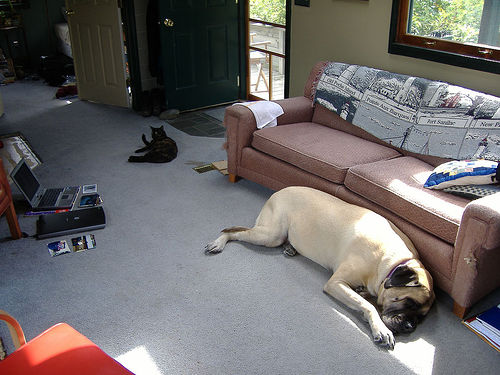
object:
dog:
[205, 186, 435, 351]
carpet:
[0, 78, 498, 374]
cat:
[128, 125, 177, 163]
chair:
[1, 313, 135, 374]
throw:
[311, 60, 499, 162]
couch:
[222, 60, 499, 321]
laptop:
[10, 156, 81, 212]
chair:
[248, 30, 275, 93]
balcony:
[249, 0, 286, 100]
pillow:
[423, 160, 499, 191]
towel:
[233, 101, 285, 130]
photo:
[47, 241, 71, 257]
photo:
[69, 233, 98, 252]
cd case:
[79, 193, 98, 208]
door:
[145, 0, 249, 113]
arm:
[1, 311, 29, 348]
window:
[388, 0, 499, 76]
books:
[461, 302, 500, 352]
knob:
[160, 17, 174, 26]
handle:
[421, 39, 436, 47]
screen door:
[244, 0, 286, 102]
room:
[1, 1, 500, 373]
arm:
[224, 97, 314, 182]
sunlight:
[385, 168, 499, 224]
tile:
[161, 101, 227, 140]